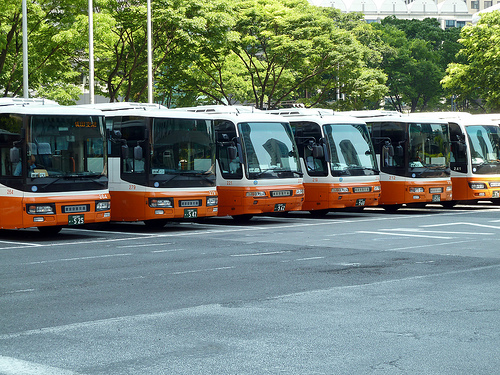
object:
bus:
[69, 102, 220, 228]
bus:
[261, 109, 382, 216]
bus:
[169, 105, 305, 221]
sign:
[75, 121, 97, 127]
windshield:
[151, 118, 216, 180]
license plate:
[184, 209, 198, 219]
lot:
[4, 200, 498, 373]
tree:
[91, 0, 383, 111]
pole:
[146, 2, 151, 105]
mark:
[230, 250, 291, 256]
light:
[151, 200, 172, 206]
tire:
[143, 219, 169, 227]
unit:
[71, 101, 169, 111]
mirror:
[134, 146, 143, 160]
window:
[111, 117, 146, 174]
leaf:
[127, 14, 142, 17]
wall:
[322, 0, 469, 20]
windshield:
[237, 121, 302, 180]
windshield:
[323, 123, 379, 177]